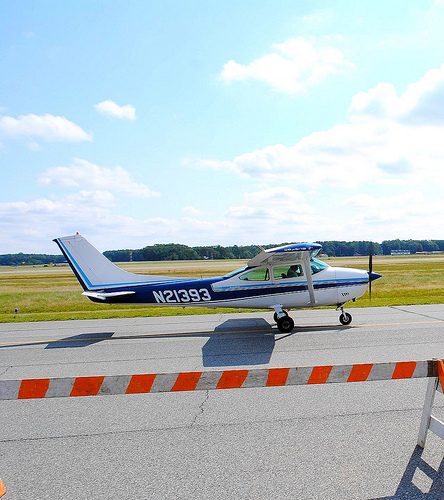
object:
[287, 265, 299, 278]
man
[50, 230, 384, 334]
plane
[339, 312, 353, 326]
wheel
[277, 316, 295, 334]
wheels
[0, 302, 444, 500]
tarmac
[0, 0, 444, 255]
sky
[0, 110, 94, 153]
clouds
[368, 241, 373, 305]
propeller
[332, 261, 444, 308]
grass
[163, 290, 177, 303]
number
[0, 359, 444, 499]
sign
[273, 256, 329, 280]
cockpit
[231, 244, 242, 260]
trees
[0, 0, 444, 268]
background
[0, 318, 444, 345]
line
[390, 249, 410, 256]
buildings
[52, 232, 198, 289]
tail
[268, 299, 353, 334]
landing gear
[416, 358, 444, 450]
sawhorse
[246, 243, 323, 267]
wing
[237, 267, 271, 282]
window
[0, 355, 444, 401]
barrier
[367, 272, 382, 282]
nose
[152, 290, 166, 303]
letter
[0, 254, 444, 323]
field